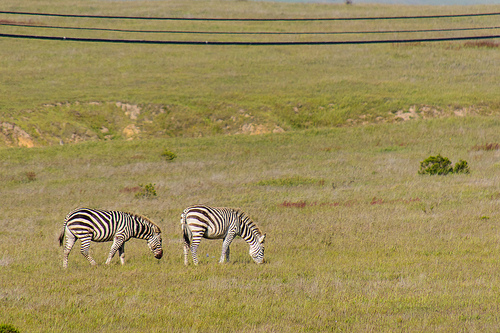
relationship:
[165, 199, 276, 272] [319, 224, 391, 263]
zebra in field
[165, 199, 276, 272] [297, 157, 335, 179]
zebra eating grass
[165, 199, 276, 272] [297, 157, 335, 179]
zebra in grass